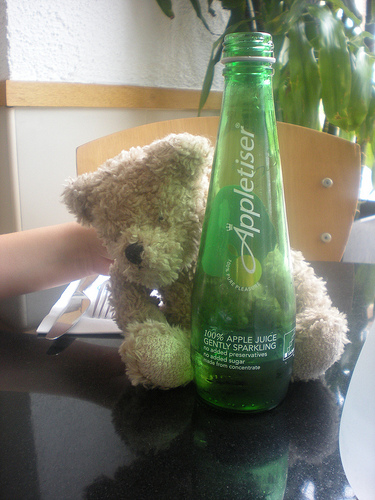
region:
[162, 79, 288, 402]
the bear holds a bottle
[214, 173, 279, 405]
the bottle is green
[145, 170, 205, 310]
the bear is tan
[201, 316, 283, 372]
the bottle was for apple juice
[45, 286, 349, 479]
the table is black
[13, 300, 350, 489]
the table is reflective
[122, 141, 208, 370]
the bear is leaning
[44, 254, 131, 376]
fork and knife on napkin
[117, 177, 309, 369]
holding the green bottle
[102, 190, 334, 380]
the bear is sitting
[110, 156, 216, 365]
the doll is brown in color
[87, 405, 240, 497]
the table is metallic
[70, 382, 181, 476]
the surface is brown in color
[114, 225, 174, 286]
the dolls mouth is white in color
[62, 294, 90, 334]
the knife is silvery in color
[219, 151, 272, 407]
the bottle is green in color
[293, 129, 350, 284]
the seat is brown in color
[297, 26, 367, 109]
the plants are green yellow in color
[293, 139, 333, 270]
the seat is wooden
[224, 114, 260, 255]
the words are written in white color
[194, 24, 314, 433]
the bottle is blue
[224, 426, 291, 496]
reflection is on the surface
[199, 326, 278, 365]
apple juice is on the bottle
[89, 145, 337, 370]
the teddybear is white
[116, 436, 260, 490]
the surface is marbled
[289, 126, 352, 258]
the chair is wooden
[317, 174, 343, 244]
rivets are on the table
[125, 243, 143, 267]
the nose is black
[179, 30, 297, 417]
the bottle is green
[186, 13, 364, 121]
a plant in the background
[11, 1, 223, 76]
a white wall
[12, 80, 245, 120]
a wooden strip on the wall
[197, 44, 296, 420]
a green bottle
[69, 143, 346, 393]
a brown teddy bear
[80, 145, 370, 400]
a teddy bear behind a green bottle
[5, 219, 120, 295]
an arm of a person holding the teddy bear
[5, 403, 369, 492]
the black counter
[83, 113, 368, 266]
a chair behind the bear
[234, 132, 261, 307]
writing on the bottle